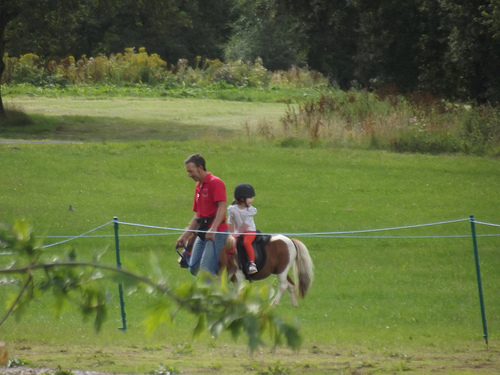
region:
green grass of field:
[0, 149, 497, 334]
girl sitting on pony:
[181, 184, 314, 307]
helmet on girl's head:
[235, 182, 255, 204]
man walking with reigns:
[175, 151, 227, 279]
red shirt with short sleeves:
[192, 173, 227, 230]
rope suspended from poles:
[1, 213, 498, 343]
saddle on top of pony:
[235, 230, 270, 273]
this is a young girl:
[214, 168, 271, 285]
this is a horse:
[172, 228, 317, 308]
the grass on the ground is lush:
[99, 171, 179, 231]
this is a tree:
[220, 0, 315, 69]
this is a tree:
[103, 6, 214, 54]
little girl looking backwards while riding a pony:
[225, 183, 259, 275]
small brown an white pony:
[177, 220, 309, 314]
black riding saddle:
[237, 231, 269, 275]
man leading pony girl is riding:
[185, 155, 228, 329]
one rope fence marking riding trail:
[10, 216, 498, 351]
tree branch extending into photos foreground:
[1, 220, 298, 362]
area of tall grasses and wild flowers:
[257, 88, 498, 148]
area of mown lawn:
[13, 147, 498, 339]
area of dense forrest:
[0, 0, 498, 103]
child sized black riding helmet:
[233, 183, 255, 200]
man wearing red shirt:
[170, 140, 218, 278]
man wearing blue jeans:
[162, 145, 231, 282]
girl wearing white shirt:
[223, 180, 263, 265]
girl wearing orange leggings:
[227, 180, 264, 269]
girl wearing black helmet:
[229, 180, 265, 275]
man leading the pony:
[174, 151, 224, 296]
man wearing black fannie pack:
[176, 141, 223, 275]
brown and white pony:
[172, 207, 314, 300]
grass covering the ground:
[15, 77, 491, 343]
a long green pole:
[463, 213, 492, 345]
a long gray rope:
[117, 206, 471, 235]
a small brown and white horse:
[165, 223, 312, 330]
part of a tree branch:
[0, 211, 309, 351]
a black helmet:
[232, 180, 259, 207]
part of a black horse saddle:
[237, 232, 265, 273]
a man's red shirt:
[183, 169, 227, 224]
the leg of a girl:
[241, 228, 258, 261]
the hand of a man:
[204, 226, 221, 243]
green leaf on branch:
[278, 318, 303, 350]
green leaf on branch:
[246, 328, 265, 355]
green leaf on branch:
[258, 283, 272, 308]